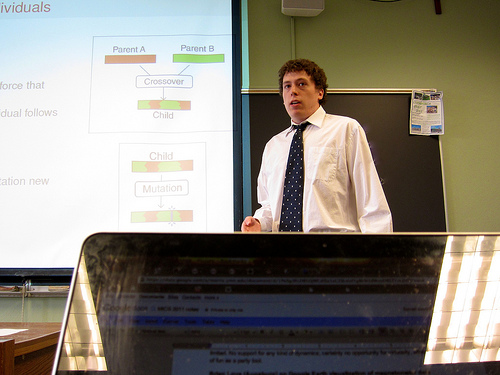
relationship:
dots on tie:
[286, 182, 303, 193] [281, 143, 306, 228]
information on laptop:
[0, 0, 241, 267] [56, 222, 498, 371]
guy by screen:
[240, 61, 393, 235] [1, 12, 259, 221]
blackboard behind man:
[236, 80, 451, 243] [253, 58, 401, 258]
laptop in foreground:
[56, 222, 498, 371] [85, 187, 434, 373]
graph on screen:
[102, 42, 224, 228] [4, 3, 241, 265]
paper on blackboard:
[407, 87, 445, 138] [236, 88, 448, 233]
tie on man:
[277, 124, 313, 231] [245, 54, 396, 233]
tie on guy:
[277, 124, 313, 231] [237, 45, 409, 232]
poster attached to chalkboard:
[408, 90, 445, 137] [340, 95, 447, 231]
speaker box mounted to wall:
[271, 0, 325, 19] [243, 7, 499, 232]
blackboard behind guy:
[236, 88, 448, 233] [240, 61, 393, 235]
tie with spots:
[277, 124, 313, 231] [279, 120, 311, 230]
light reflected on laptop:
[422, 234, 498, 368] [67, 240, 498, 365]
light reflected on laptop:
[55, 249, 105, 372] [67, 240, 498, 365]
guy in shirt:
[240, 61, 393, 235] [241, 112, 396, 226]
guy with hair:
[240, 61, 393, 235] [267, 49, 337, 102]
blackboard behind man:
[236, 88, 448, 233] [245, 54, 396, 233]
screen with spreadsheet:
[4, 3, 241, 265] [0, 0, 228, 229]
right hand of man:
[239, 216, 261, 231] [245, 54, 396, 233]